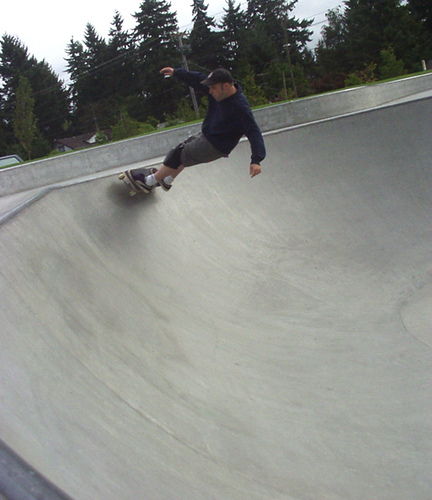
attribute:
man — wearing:
[132, 59, 276, 204]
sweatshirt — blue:
[196, 98, 254, 160]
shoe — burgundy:
[129, 172, 151, 194]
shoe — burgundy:
[152, 167, 174, 191]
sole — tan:
[149, 170, 165, 191]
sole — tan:
[128, 171, 148, 193]